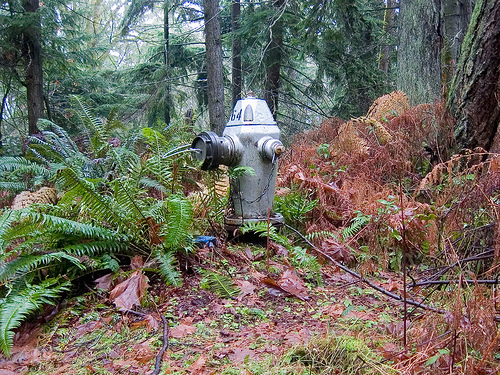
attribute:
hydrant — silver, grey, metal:
[183, 92, 299, 246]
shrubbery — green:
[27, 126, 177, 269]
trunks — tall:
[199, 0, 233, 120]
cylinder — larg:
[190, 126, 236, 183]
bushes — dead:
[300, 103, 453, 180]